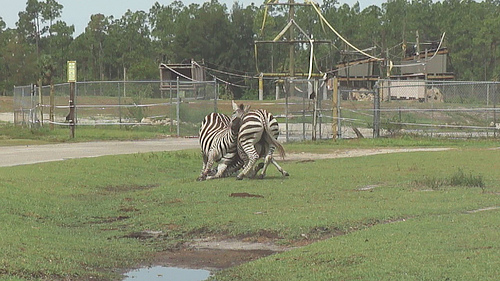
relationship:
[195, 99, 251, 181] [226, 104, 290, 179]
zebra rubbing against zebra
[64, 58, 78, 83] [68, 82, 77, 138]
sign on post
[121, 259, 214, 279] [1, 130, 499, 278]
water in grass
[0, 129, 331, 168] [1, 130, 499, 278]
road near grass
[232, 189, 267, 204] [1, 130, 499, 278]
dirt in grass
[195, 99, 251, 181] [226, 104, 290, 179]
zebra leaning on zebra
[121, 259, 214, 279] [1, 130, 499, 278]
water on grass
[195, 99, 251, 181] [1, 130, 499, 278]
zebra on grass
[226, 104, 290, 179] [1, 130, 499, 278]
zebra on grass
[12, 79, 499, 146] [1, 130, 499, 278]
fence around grass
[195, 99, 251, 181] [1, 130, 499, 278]
zebra in grass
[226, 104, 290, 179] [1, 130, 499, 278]
zebra in grass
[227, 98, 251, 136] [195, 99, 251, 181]
head of zebra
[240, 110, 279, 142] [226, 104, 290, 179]
rear end of zebra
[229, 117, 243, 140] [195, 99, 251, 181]
snout of zebra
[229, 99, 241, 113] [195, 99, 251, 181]
ear of zebra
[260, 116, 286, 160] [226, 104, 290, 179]
tail of zebra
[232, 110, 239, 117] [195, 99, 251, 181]
eye of zebra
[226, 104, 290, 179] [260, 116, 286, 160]
zebra has tail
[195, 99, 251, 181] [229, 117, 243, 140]
zebra has snout